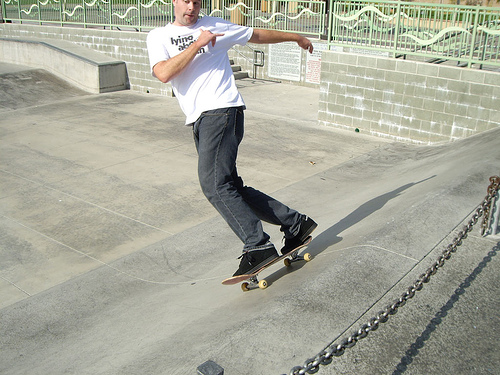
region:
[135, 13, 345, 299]
One man is seen.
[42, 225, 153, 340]
Ground is grey color.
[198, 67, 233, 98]
Man is wearing white shirt.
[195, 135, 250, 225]
Pant is grey color.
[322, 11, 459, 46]
Rails are green color.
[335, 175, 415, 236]
Shadow falls on ground.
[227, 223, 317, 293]
Shoes are black color.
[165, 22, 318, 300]
Man is skating.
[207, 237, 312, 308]
Skate board is black and brown color.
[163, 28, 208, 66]
letters are black color.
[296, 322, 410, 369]
a gray barrier with links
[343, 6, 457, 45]
portion of light green gate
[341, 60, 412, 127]
gray cement wall with squares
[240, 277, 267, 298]
two wheels on skateboard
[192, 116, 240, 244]
blue jeans worn by man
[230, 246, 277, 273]
black shoes on man's foot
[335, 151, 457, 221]
a portion of the skateboard ramp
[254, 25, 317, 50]
an arm of the man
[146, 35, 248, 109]
white shirt on the man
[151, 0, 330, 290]
the man on dark skateboard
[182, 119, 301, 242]
the jeans are green in color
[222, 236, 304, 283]
the shoes are black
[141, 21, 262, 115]
the shirt is white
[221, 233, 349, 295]
the skateboard has four wheels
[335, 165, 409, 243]
there is a shadow on the ramp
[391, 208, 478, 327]
the chain is metallic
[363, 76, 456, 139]
the wall has grey bricks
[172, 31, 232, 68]
there is black writing on the shirt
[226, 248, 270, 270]
the shoe has black laces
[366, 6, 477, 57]
the rails are mettalic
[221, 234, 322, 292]
Tan skateboard under man's feet.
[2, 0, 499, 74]
White metal fence on gray brick wall.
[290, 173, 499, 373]
Linked metal chain on the side of park.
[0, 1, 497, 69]
White metal fence securing the skate park.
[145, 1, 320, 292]
Man in white t-shirt on a skateboard.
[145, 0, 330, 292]
Man skateboarding in a skate park.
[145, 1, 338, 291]
Man in white t-shirt skating on a board.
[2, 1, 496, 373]
Man skateboarding on concrete surface in a park.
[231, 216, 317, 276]
Black athletic shoes on skateboarder's feet.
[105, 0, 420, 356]
Man skating on the ramp at the skate park.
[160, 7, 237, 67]
Man wearing white shirt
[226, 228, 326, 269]
Man wearing black tennis shoes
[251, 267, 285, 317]
Light wheels on skateboard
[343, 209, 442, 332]
Silver chain near skateboarder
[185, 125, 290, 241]
Man wearing blue jeans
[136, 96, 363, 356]
Man skateboarding on ramp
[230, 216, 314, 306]
Man standing on skateboard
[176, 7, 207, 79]
Black writing on man's shirt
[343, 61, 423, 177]
Gray wall behind skateboarder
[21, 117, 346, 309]
Ground is concrete